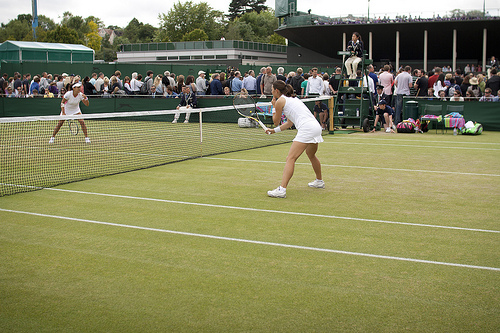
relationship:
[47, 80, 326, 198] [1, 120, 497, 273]
players are on tennis court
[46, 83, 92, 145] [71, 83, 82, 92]
player wearing hat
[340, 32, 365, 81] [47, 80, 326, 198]
judge watching players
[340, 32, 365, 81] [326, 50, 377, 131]
judge sitting on ladder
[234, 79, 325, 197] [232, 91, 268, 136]
player has tennis racket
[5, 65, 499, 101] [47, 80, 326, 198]
people are watching players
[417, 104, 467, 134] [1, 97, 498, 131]
chairs are against wall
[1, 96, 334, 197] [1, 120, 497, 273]
net on tennis court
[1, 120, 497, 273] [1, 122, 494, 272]
tennis court has lines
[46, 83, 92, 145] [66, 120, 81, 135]
player holding tennis racket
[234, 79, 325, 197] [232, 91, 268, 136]
player holding tennis racket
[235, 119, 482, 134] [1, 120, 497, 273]
bags are on side of tennis court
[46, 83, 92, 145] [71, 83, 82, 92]
player wearing a hat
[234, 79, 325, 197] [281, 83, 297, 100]
player has a ponytail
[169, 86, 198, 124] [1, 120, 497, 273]
man sitting next to tennis court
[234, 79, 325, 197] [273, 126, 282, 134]
player has a wristband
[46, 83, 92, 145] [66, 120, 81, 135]
player has a tennis racket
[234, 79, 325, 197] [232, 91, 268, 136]
player has a tennis racket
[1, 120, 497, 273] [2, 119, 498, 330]
tennis court made of grass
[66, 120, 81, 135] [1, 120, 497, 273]
tennis racket near tennis court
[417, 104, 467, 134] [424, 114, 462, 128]
chairs are draped with towels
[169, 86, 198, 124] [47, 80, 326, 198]
man watching players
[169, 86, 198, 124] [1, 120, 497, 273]
man sitting on side of tennis court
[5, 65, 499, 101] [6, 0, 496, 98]
people are moving in stands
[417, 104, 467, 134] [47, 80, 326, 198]
chairs are ready for players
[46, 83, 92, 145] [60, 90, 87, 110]
player has shirt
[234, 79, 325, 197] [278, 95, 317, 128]
player has shirt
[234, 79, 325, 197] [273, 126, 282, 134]
player has wristband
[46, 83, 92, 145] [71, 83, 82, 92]
player has hat